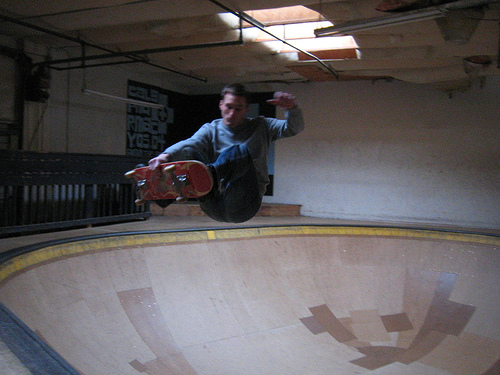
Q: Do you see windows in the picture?
A: Yes, there is a window.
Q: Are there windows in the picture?
A: Yes, there is a window.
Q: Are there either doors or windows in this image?
A: Yes, there is a window.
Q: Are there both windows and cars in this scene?
A: No, there is a window but no cars.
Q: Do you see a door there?
A: No, there are no doors.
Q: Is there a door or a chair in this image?
A: No, there are no doors or chairs.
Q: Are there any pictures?
A: No, there are no pictures.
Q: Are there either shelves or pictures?
A: No, there are no pictures or shelves.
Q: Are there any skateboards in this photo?
A: Yes, there is a skateboard.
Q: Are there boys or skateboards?
A: Yes, there is a skateboard.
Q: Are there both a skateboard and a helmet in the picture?
A: No, there is a skateboard but no helmets.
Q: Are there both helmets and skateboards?
A: No, there is a skateboard but no helmets.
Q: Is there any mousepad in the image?
A: No, there are no mouse pads.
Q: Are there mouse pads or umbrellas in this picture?
A: No, there are no mouse pads or umbrellas.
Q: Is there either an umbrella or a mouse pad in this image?
A: No, there are no mouse pads or umbrellas.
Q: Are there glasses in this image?
A: No, there are no glasses.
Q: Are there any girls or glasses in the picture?
A: No, there are no glasses or girls.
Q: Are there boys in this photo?
A: No, there are no boys.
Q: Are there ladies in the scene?
A: No, there are no ladies.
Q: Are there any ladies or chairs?
A: No, there are no ladies or chairs.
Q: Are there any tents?
A: No, there are no tents.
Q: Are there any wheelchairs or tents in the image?
A: No, there are no tents or wheelchairs.